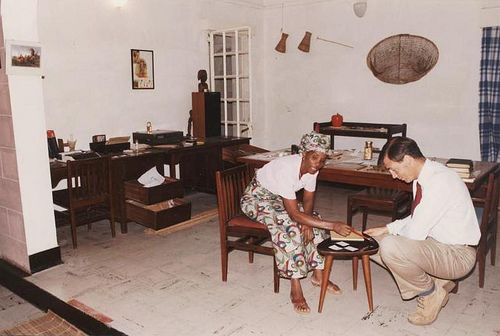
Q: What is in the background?
A: Walls.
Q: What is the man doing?
A: Examining an item with a woman.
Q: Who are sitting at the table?
A: A man and woman.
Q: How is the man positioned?
A: Crouching.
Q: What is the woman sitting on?
A: A chair.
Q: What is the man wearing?
A: A white shirt.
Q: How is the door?
A: Closed.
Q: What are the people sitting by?
A: A table.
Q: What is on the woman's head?
A: Cloth.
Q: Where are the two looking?
A: At a small table.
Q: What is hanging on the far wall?
A: A picture.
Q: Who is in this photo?
A: A man and woman.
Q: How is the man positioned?
A: Crouching.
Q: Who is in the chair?
A: The woman.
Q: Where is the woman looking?
A: Toward the camera.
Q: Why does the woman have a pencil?
A: She's taking notes.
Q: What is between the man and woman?
A: A three-legged stool.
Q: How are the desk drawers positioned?
A: Open.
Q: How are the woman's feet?
A: Bare.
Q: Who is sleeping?
A: No one.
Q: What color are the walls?
A: White.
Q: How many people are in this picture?
A: 2.